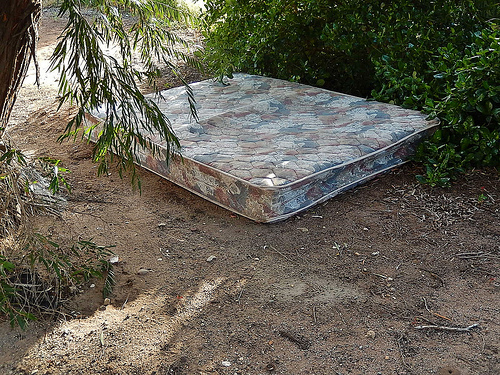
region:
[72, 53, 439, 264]
a mattress on the ground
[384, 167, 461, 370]
dirt on the ground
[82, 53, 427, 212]
A mattress on the ground.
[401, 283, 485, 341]
A stick on the ground.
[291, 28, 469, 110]
Tree next to the mattress.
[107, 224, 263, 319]
Dirt on the ground.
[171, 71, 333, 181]
The mattress is dirty.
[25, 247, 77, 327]
Branches on the ground.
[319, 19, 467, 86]
The tree is green.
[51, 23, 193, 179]
Leaves on the branches.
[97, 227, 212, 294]
Rocks on the ground.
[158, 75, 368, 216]
The mattress is on the dirt.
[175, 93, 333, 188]
Multo color mattress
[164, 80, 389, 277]
Multo color mattress kept above the dirt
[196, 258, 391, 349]
Dirt near the mattress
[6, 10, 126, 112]
Tree near the mattress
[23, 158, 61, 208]
Roots of the tree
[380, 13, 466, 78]
Plants near the mattress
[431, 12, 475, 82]
Green leaves of the plants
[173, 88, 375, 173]
Big size mattress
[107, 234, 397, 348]
Dirt with full of sands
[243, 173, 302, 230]
Corner of the mattress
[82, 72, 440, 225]
abandoned matress on the ground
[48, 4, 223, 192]
tree branch and leaves hanging down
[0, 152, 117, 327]
branches on the ground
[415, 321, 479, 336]
stick on the ground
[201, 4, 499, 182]
green buch behind the mattress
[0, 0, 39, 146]
trunk of a tree in the upper left corner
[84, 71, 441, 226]
queen size matress in the dirt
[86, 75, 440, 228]
the mattress is being tossed out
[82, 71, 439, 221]
floral design on the matress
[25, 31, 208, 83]
area of sunlight on the ground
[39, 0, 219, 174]
a few leaf covered branches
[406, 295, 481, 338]
a few sticks on the ground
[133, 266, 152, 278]
a small rock in the sand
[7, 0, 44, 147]
a gnarled tree trunk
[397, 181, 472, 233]
a pile of dead leaves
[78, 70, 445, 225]
an old discarded mattress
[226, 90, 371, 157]
a colorful floral print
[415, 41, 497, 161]
a few dark green leaves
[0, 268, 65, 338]
a hole in the dirt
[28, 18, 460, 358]
a dirt pathway